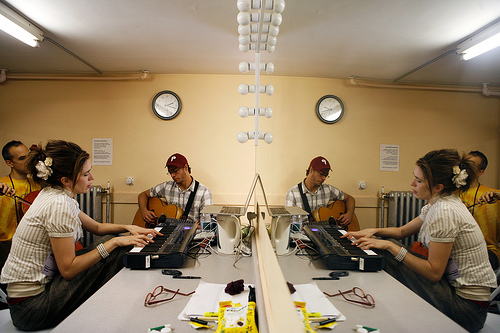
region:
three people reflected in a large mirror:
[2, 2, 493, 332]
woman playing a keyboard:
[2, 140, 202, 324]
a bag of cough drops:
[210, 292, 255, 332]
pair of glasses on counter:
[127, 277, 197, 310]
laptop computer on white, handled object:
[205, 160, 269, 255]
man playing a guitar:
[130, 149, 210, 231]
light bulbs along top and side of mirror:
[235, 2, 290, 152]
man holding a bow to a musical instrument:
[0, 133, 60, 244]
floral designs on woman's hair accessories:
[35, 142, 88, 190]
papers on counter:
[176, 273, 258, 330]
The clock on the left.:
[149, 85, 184, 122]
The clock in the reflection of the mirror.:
[315, 91, 347, 125]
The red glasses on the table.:
[142, 276, 189, 312]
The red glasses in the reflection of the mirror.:
[323, 277, 373, 307]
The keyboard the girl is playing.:
[134, 213, 194, 266]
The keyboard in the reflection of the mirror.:
[292, 211, 383, 275]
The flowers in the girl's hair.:
[32, 156, 57, 178]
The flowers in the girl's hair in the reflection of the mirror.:
[447, 162, 467, 189]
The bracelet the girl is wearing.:
[94, 234, 114, 264]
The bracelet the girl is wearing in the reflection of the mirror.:
[390, 240, 408, 264]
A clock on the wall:
[312, 87, 342, 125]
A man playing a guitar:
[280, 154, 366, 239]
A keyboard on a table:
[116, 202, 202, 277]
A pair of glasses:
[139, 282, 195, 308]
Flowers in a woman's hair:
[29, 153, 59, 182]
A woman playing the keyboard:
[1, 136, 163, 324]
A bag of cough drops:
[212, 297, 261, 332]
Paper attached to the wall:
[87, 134, 116, 169]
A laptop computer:
[195, 172, 259, 227]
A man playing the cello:
[0, 134, 54, 262]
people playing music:
[0, 109, 255, 329]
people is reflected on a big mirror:
[228, 0, 498, 332]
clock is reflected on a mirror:
[308, 85, 349, 126]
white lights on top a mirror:
[228, 0, 263, 156]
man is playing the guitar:
[121, 152, 235, 247]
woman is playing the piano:
[1, 139, 204, 323]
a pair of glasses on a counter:
[121, 273, 196, 318]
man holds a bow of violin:
[1, 135, 49, 248]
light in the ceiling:
[0, 2, 53, 59]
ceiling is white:
[0, 4, 242, 79]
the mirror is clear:
[31, 73, 297, 331]